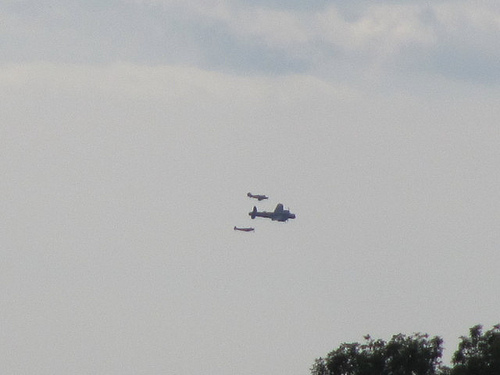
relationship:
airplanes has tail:
[249, 203, 295, 221] [247, 204, 258, 222]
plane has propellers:
[245, 189, 268, 203] [265, 193, 271, 202]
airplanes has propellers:
[249, 203, 295, 221] [283, 205, 293, 224]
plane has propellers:
[232, 223, 256, 236] [251, 223, 257, 233]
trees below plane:
[308, 323, 497, 375] [245, 189, 268, 203]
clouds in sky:
[220, 4, 499, 73] [2, 3, 500, 374]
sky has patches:
[2, 3, 500, 374] [3, 2, 500, 98]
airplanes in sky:
[233, 190, 299, 237] [2, 3, 500, 374]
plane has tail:
[245, 189, 268, 203] [245, 189, 253, 198]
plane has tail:
[232, 223, 256, 236] [232, 223, 239, 233]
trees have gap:
[308, 323, 497, 375] [436, 326, 461, 371]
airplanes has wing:
[249, 203, 295, 221] [273, 201, 287, 217]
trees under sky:
[308, 323, 497, 375] [2, 3, 500, 374]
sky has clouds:
[2, 3, 500, 374] [220, 4, 499, 73]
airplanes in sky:
[249, 203, 295, 221] [2, 3, 500, 374]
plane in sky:
[245, 189, 268, 203] [2, 3, 500, 374]